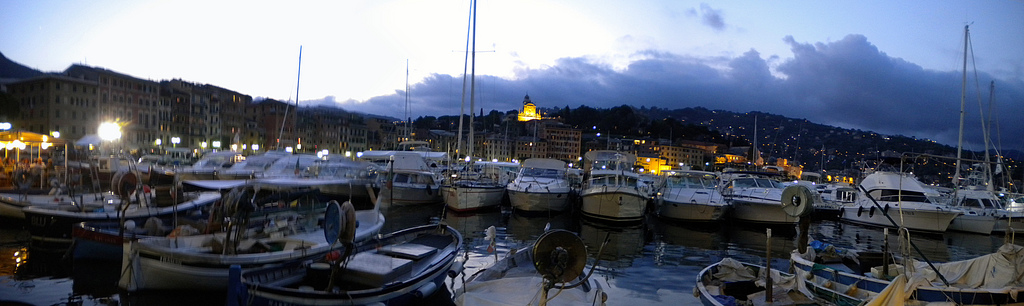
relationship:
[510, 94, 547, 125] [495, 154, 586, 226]
light above boat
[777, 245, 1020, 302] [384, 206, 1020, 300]
boat on water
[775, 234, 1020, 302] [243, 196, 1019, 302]
boat on water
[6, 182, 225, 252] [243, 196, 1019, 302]
boat on water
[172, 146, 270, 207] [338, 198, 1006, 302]
boat on water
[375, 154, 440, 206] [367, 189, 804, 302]
boat on water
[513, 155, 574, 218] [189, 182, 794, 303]
boat on water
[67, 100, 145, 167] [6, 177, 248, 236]
light attached to boat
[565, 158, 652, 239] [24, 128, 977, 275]
boat docked in water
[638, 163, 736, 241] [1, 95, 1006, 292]
boat docked in water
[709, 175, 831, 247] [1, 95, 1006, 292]
boat docked in water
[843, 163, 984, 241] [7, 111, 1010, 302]
boat docked in water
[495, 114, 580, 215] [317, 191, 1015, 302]
boat docked in water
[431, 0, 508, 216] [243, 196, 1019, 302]
boat docked in water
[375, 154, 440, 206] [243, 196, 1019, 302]
boat docked in water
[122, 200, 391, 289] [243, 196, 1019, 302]
boat docked in water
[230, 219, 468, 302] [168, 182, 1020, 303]
boat docked in water